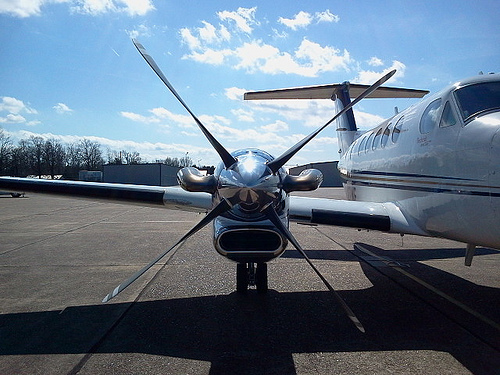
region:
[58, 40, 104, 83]
Blue clear skies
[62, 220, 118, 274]
Surface with tarmac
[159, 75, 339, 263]
A plane in the airport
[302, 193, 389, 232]
A wing of the plane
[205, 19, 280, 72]
White clouds in the skies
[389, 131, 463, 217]
A white colored plane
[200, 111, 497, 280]
Two planes in the airport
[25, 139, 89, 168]
Trees growing in the background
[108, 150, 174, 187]
Building in the background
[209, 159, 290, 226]
Propeller on the plane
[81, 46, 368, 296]
propeller on white plane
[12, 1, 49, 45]
white clouds in blue sky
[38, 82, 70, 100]
white clouds in blue sky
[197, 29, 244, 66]
white clouds in blue sky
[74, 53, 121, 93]
white clouds in blue sky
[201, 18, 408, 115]
a sky that is blue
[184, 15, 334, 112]
a sky with clouds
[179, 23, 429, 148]
a sky with white clouds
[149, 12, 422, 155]
a blue sky with clouds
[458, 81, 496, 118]
window on a plane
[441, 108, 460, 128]
window on a plane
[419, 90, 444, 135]
window on a plane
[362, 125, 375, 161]
window on a plane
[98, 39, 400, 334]
an air planes propeller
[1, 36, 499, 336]
an airplane on black asphalt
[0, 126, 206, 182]
black trees with no leaves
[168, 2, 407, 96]
a clump of clouds in the sky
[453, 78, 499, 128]
the window of a plane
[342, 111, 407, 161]
a row of passenger windows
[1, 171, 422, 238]
a long plane wing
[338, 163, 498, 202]
stripes on the side of a plane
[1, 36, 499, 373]
a plane with a shadow under it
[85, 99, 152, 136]
white clouds in blue sky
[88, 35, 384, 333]
large airplane propeller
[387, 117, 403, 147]
window on a plane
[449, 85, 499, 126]
windshield on a plane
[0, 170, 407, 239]
wing of a plane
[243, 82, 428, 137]
tail fin of a plane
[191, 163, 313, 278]
engine on a plane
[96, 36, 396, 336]
the propeller is large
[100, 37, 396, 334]
the propeller is still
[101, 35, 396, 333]
the propeller is black and white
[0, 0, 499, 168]
the clouds are white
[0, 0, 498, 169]
the clouds in the sky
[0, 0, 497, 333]
the sky above the airplane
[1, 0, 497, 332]
the clouds above the airplane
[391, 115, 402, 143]
the window is small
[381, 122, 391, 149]
the window is small